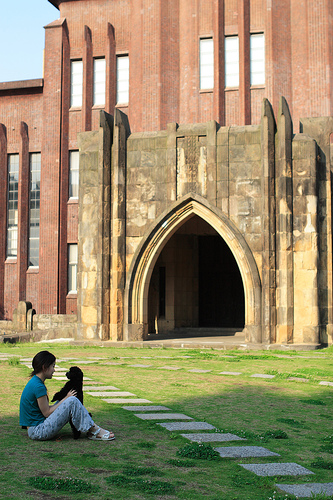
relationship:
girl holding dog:
[17, 349, 115, 442] [51, 367, 84, 403]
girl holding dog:
[18, 344, 118, 446] [50, 360, 95, 438]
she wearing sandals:
[17, 348, 118, 442] [92, 425, 116, 441]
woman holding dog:
[19, 350, 116, 441] [51, 366, 93, 436]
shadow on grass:
[1, 409, 331, 497] [120, 348, 331, 498]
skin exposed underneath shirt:
[23, 425, 31, 431] [17, 375, 49, 424]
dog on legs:
[49, 363, 82, 405] [66, 419, 78, 434]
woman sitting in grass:
[19, 350, 116, 441] [5, 442, 331, 497]